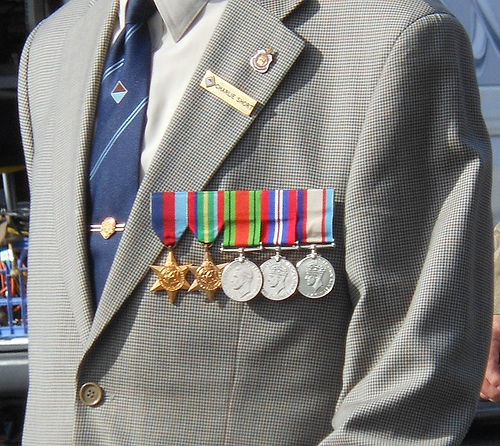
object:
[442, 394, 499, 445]
tomato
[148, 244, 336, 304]
pendant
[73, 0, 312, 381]
lapel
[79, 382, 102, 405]
button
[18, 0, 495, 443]
jacket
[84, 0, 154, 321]
tie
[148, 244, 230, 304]
star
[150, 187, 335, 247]
ribbon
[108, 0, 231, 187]
shirt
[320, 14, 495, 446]
sleeve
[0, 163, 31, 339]
blender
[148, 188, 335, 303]
medal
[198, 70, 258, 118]
name tag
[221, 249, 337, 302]
coins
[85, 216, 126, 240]
diamond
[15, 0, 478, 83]
shoulders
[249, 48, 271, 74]
pin